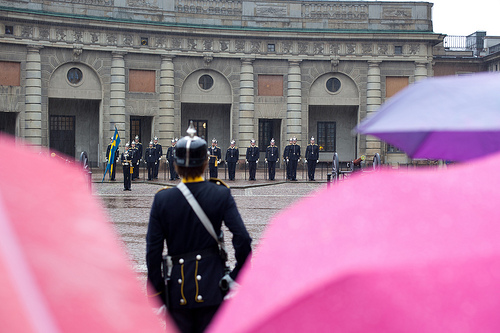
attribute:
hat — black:
[171, 117, 212, 165]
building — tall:
[2, 1, 446, 166]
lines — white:
[89, 172, 317, 194]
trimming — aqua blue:
[0, 0, 449, 40]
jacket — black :
[142, 180, 252, 310]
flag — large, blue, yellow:
[104, 122, 124, 183]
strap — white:
[176, 182, 226, 247]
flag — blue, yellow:
[98, 125, 127, 185]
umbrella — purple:
[346, 70, 498, 165]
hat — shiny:
[139, 113, 234, 188]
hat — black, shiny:
[128, 106, 210, 185]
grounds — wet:
[74, 167, 326, 302]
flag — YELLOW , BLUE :
[103, 123, 120, 179]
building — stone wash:
[20, 11, 407, 147]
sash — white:
[181, 184, 218, 246]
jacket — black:
[156, 182, 224, 306]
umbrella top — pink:
[201, 151, 492, 329]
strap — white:
[167, 175, 226, 253]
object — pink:
[306, 235, 411, 275]